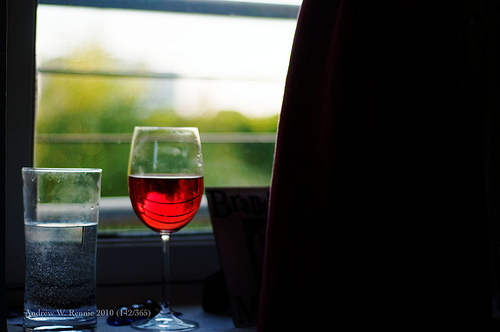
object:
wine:
[127, 174, 204, 234]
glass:
[128, 126, 206, 331]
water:
[24, 222, 99, 322]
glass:
[20, 165, 103, 332]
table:
[6, 305, 238, 331]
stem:
[160, 232, 171, 310]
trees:
[35, 42, 281, 187]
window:
[32, 0, 303, 242]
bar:
[34, 194, 210, 220]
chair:
[255, 0, 500, 332]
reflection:
[130, 179, 203, 231]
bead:
[114, 306, 133, 317]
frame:
[199, 186, 271, 328]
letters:
[206, 187, 269, 218]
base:
[129, 311, 202, 332]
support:
[200, 269, 231, 317]